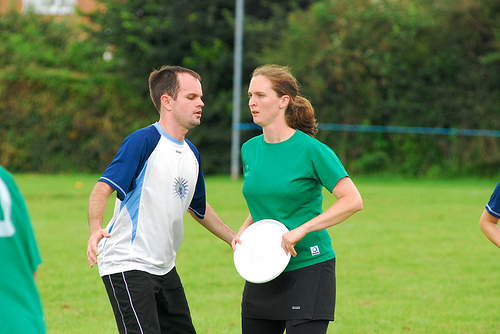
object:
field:
[68, 33, 469, 295]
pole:
[322, 122, 496, 134]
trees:
[2, 0, 74, 175]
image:
[166, 164, 205, 207]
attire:
[104, 124, 206, 332]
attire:
[230, 127, 359, 328]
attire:
[1, 155, 45, 331]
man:
[75, 60, 234, 334]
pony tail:
[285, 93, 319, 135]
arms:
[77, 127, 154, 266]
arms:
[178, 139, 233, 249]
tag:
[312, 241, 322, 256]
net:
[235, 121, 495, 188]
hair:
[245, 64, 324, 129]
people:
[214, 57, 372, 334]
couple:
[82, 60, 364, 331]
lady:
[229, 62, 364, 332]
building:
[1, 0, 116, 26]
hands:
[279, 229, 302, 257]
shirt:
[93, 120, 205, 279]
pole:
[233, 0, 245, 183]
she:
[229, 63, 368, 332]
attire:
[243, 257, 342, 320]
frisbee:
[234, 218, 293, 283]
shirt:
[239, 128, 349, 272]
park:
[8, 11, 489, 326]